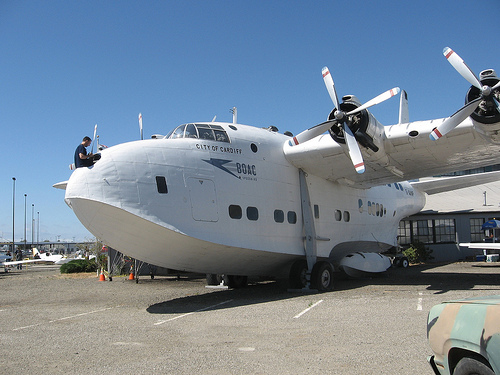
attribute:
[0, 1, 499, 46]
sky — blue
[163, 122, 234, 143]
cockpit — white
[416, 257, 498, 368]
vehicle — camoflauge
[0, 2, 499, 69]
sky — blue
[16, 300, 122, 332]
markings — white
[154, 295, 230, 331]
markings — white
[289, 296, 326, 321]
markings — white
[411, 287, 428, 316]
markings — white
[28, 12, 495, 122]
sky — blue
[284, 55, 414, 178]
propeller — large, red, white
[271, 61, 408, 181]
propeller — white, red, large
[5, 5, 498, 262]
sky — blue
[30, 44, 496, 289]
airplane — large, white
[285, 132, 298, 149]
line — blue, red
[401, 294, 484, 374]
vehicle — camouflage 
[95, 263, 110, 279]
traffic cone — orange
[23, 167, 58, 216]
clouds — white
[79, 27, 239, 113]
sky — blue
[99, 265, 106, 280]
traffic cone — fluorescent orange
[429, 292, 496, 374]
truck — camoflauge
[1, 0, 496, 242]
sky — blue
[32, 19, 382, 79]
sky — white, blue